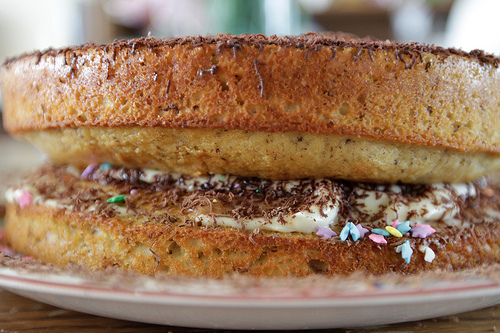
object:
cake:
[2, 32, 499, 298]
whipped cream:
[17, 165, 499, 233]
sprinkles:
[107, 194, 125, 203]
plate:
[1, 268, 498, 330]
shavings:
[36, 171, 499, 228]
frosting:
[120, 167, 244, 194]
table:
[2, 289, 499, 332]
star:
[368, 233, 387, 243]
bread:
[4, 36, 497, 183]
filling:
[29, 160, 499, 232]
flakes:
[396, 220, 410, 234]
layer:
[2, 37, 496, 189]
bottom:
[3, 192, 499, 284]